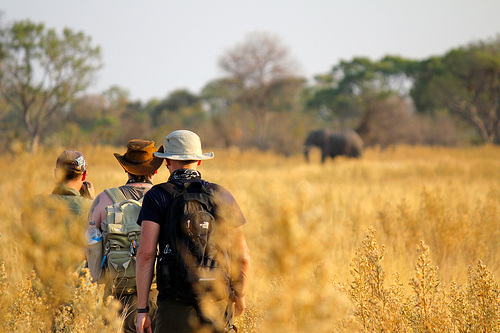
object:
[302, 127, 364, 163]
elephant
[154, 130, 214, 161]
hat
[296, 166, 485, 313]
grass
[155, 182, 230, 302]
backpack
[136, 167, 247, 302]
shirt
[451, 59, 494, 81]
leaves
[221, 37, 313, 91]
tree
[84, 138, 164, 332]
men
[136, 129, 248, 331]
man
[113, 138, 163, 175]
cap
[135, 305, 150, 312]
watch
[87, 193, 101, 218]
tattoo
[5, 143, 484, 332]
plain